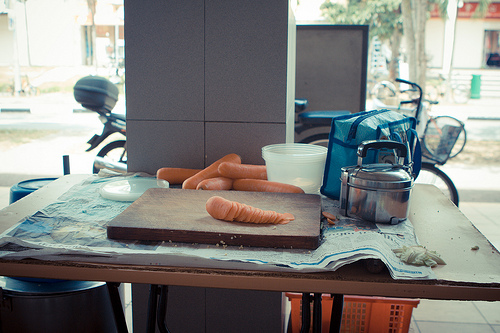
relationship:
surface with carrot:
[0, 174, 500, 301] [207, 192, 294, 223]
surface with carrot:
[0, 174, 500, 301] [155, 152, 307, 192]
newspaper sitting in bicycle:
[431, 121, 461, 165] [393, 79, 466, 209]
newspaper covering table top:
[2, 169, 439, 281] [2, 170, 484, 304]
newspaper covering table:
[2, 169, 439, 281] [13, 196, 335, 328]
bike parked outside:
[68, 72, 126, 173] [2, 2, 484, 331]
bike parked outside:
[293, 94, 353, 147] [2, 2, 484, 331]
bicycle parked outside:
[393, 79, 466, 209] [2, 2, 484, 331]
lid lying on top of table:
[100, 177, 169, 201] [0, 172, 499, 331]